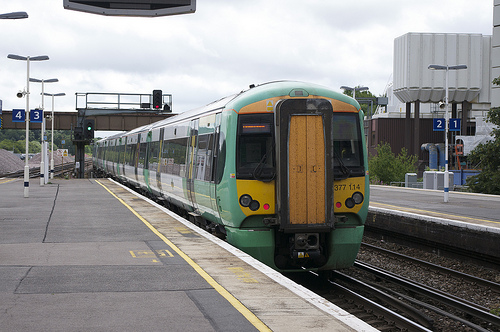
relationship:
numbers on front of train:
[329, 179, 361, 193] [84, 78, 371, 274]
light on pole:
[428, 59, 468, 73] [443, 73, 452, 204]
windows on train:
[93, 132, 217, 183] [84, 78, 371, 274]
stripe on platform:
[91, 177, 272, 330] [1, 176, 381, 330]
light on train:
[239, 191, 261, 213] [84, 78, 371, 274]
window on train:
[235, 111, 275, 182] [84, 78, 371, 274]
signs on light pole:
[431, 116, 461, 135] [425, 63, 469, 202]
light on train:
[258, 200, 273, 213] [84, 78, 371, 274]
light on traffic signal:
[83, 126, 93, 133] [80, 115, 94, 143]